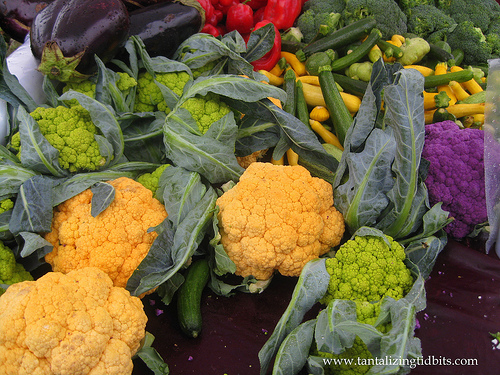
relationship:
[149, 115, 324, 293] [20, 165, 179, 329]
leaves on cauliflower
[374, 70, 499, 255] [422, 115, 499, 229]
leaves on cauliflower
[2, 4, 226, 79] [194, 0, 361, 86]
eggplant near peppers